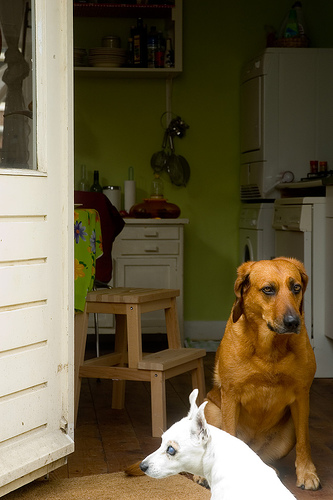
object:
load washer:
[238, 196, 276, 273]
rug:
[0, 461, 211, 499]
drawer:
[120, 224, 181, 242]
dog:
[138, 385, 296, 499]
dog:
[124, 255, 323, 491]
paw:
[292, 454, 321, 490]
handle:
[144, 228, 157, 240]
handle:
[142, 244, 160, 255]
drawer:
[117, 241, 182, 259]